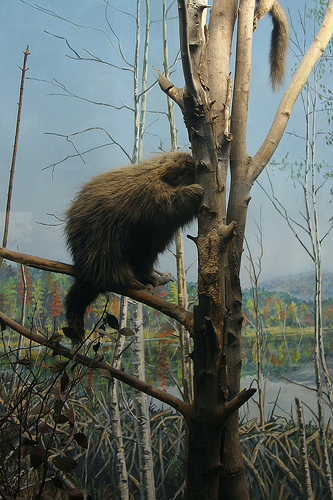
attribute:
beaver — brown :
[42, 149, 235, 328]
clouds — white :
[0, 148, 332, 286]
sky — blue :
[1, 0, 331, 286]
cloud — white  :
[5, 15, 41, 46]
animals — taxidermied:
[53, 0, 296, 349]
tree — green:
[245, 290, 262, 333]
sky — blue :
[1, 1, 331, 432]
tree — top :
[168, 25, 332, 360]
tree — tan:
[149, 0, 332, 494]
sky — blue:
[261, 208, 272, 227]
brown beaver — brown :
[78, 139, 212, 283]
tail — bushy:
[53, 275, 137, 352]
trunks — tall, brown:
[163, 11, 276, 489]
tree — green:
[284, 297, 303, 328]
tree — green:
[28, 277, 42, 324]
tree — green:
[0, 274, 18, 316]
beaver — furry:
[61, 148, 208, 351]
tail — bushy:
[267, 1, 290, 94]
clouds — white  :
[10, 8, 287, 206]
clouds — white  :
[264, 181, 314, 265]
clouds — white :
[263, 174, 321, 259]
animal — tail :
[51, 148, 227, 342]